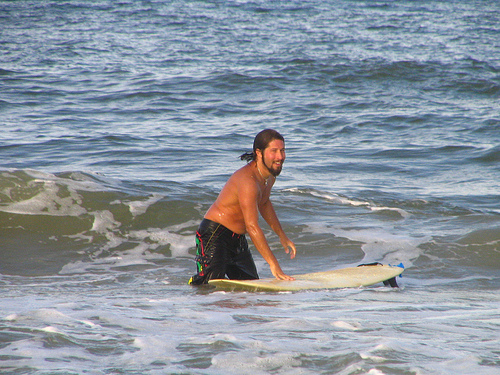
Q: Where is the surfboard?
A: On the water.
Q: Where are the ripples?
A: In the water.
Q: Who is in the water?
A: Surfer.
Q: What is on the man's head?
A: Ponytail.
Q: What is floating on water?
A: Surfboard.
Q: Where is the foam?
A: On water.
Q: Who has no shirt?
A: Surfer.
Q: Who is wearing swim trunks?
A: Surfer.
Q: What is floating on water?
A: Surfboard.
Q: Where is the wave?
A: In the water.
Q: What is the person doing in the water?
A: Preparing to surf.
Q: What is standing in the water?
A: The man.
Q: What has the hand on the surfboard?
A: The man.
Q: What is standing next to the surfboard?
A: The man.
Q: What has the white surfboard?
A: The man.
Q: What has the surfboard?
A: The man.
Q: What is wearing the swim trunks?
A: The man.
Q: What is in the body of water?
A: The man.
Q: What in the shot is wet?
A: The man.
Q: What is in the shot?
A: The body of water.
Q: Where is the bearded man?
A: In the ocean.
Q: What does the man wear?
A: He is shirtless with swimming trunks.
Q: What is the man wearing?
A: A pair of shorts.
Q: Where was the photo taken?
A: In the ocean.